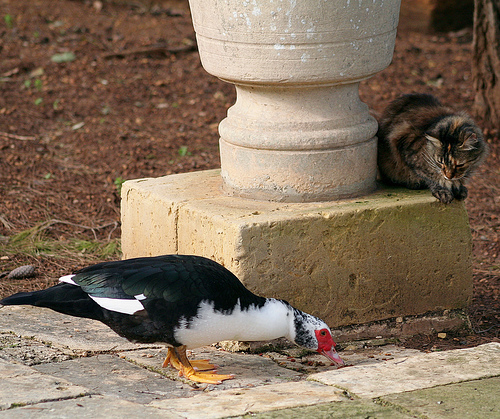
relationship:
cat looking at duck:
[378, 93, 484, 208] [0, 255, 344, 388]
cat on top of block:
[378, 93, 484, 208] [119, 169, 473, 353]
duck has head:
[0, 255, 344, 388] [295, 313, 335, 351]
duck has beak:
[0, 255, 344, 388] [325, 347, 342, 367]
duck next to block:
[0, 255, 344, 388] [119, 169, 473, 353]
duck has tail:
[0, 255, 344, 388] [2, 285, 75, 314]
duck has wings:
[0, 255, 344, 388] [65, 264, 177, 299]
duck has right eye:
[0, 255, 344, 388] [319, 328, 331, 338]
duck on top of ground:
[0, 255, 344, 388] [1, 2, 496, 413]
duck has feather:
[0, 255, 344, 388] [164, 281, 192, 302]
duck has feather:
[0, 255, 344, 388] [238, 315, 262, 328]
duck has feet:
[0, 255, 344, 388] [161, 343, 233, 387]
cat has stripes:
[378, 93, 484, 208] [378, 94, 430, 141]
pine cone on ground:
[8, 263, 38, 280] [1, 2, 496, 413]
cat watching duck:
[378, 93, 484, 208] [0, 255, 344, 388]